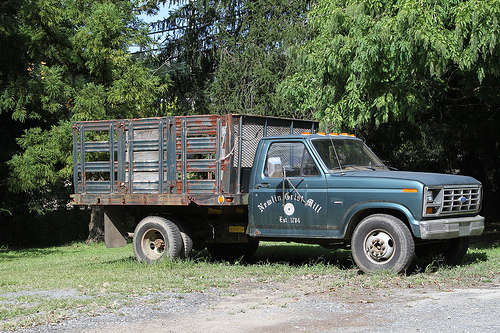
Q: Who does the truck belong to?
A: Newlin Grist Mill.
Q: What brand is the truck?
A: Ford.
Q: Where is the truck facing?
A: Right.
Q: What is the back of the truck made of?
A: Steel rails.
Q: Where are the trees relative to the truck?
A: Above the truck.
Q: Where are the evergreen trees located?
A: Behind and above the truck.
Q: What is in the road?
A: Gravel.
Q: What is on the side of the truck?
A: White letters.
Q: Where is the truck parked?
A: In the grass.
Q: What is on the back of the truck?
A: Railing.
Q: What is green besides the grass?
A: The truck.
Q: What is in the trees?
A: Electriclal lines.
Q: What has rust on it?
A: The truck.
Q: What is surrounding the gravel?
A: Dirt.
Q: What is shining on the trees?
A: Sun.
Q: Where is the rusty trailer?
A: The rusty trailer is on the old truck.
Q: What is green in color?
A: The old truck is green.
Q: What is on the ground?
A: There is grass and patches of gravel on the ground.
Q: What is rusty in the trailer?
A: The railing is rusty.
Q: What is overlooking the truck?
A: A tree with dense foliage is overlooking the truck.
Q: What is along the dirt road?
A: There are patches of grass along the dirt road.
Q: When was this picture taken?
A: Afternoon.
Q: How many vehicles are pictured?
A: One.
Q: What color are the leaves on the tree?
A: Green.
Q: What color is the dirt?
A: Brown.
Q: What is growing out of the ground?
A: Grass and trees.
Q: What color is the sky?
A: Blue.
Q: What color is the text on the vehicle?
A: White.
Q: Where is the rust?
A: On the vehicle.